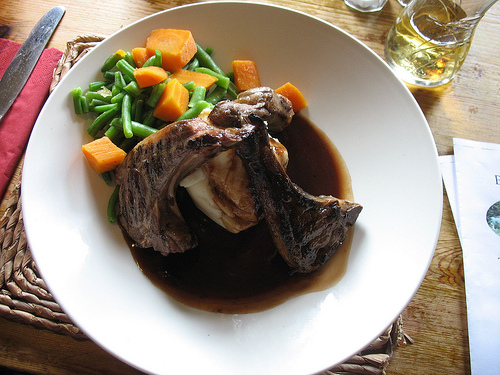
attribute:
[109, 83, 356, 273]
meat — cooked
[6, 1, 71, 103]
knife — silver, scratched, butter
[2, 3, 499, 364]
table — brown, wooden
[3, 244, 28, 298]
pad — hot-item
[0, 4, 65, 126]
knife — silver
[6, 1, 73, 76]
knife — butter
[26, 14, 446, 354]
bowl — white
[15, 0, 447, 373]
plate — white 